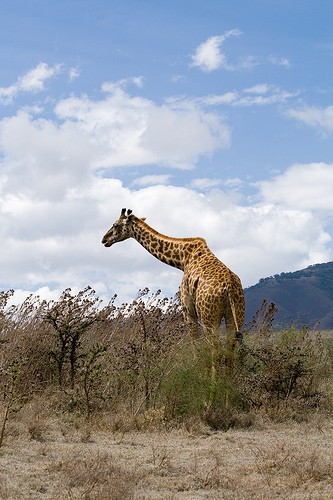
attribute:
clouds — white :
[106, 138, 153, 195]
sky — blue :
[125, 18, 170, 50]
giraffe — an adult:
[97, 206, 255, 419]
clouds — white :
[140, 108, 204, 159]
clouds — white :
[0, 29, 333, 303]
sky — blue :
[0, 0, 330, 207]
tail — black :
[226, 285, 246, 358]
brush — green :
[166, 348, 245, 414]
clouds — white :
[190, 36, 235, 80]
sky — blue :
[2, 28, 330, 263]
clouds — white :
[206, 152, 332, 256]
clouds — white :
[0, 65, 171, 283]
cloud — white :
[192, 31, 291, 73]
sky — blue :
[0, 1, 329, 321]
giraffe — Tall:
[168, 225, 251, 333]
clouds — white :
[1, 74, 100, 275]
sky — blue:
[0, 0, 188, 52]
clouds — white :
[4, 108, 178, 170]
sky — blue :
[1, 1, 331, 268]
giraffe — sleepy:
[108, 206, 270, 356]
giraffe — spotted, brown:
[101, 206, 245, 408]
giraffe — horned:
[96, 210, 280, 377]